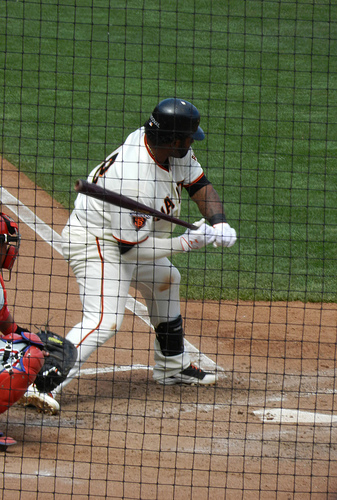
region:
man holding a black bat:
[62, 174, 250, 254]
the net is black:
[28, 184, 313, 455]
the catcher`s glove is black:
[3, 308, 90, 396]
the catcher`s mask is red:
[2, 204, 23, 265]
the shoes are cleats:
[121, 352, 227, 397]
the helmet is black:
[121, 86, 222, 164]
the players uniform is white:
[39, 73, 220, 345]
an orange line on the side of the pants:
[80, 230, 111, 354]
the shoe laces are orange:
[156, 353, 216, 385]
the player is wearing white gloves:
[164, 208, 236, 260]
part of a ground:
[169, 436, 208, 482]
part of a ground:
[278, 411, 303, 429]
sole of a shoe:
[30, 397, 48, 415]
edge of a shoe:
[184, 374, 201, 386]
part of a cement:
[244, 450, 268, 468]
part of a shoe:
[206, 368, 219, 385]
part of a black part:
[189, 363, 205, 379]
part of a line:
[152, 396, 188, 431]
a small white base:
[250, 404, 336, 428]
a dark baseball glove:
[35, 329, 79, 393]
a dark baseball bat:
[70, 179, 205, 230]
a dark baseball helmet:
[148, 98, 209, 144]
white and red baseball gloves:
[180, 218, 215, 252]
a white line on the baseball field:
[0, 180, 228, 380]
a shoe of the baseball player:
[155, 362, 217, 387]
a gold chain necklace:
[144, 140, 156, 161]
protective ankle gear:
[152, 316, 185, 353]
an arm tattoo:
[191, 186, 224, 215]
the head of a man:
[141, 91, 210, 159]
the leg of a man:
[39, 232, 135, 387]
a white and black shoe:
[155, 356, 234, 386]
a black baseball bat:
[71, 178, 205, 230]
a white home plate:
[248, 401, 336, 426]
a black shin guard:
[152, 311, 187, 357]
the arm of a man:
[180, 156, 223, 220]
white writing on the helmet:
[147, 113, 162, 129]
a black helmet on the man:
[142, 94, 207, 141]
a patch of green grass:
[0, 0, 336, 307]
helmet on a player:
[141, 96, 211, 150]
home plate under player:
[257, 389, 319, 442]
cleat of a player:
[167, 350, 219, 392]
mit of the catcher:
[32, 328, 73, 393]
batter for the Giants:
[73, 111, 220, 305]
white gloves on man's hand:
[179, 213, 238, 255]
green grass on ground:
[241, 115, 314, 191]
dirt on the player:
[154, 265, 183, 296]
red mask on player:
[0, 193, 27, 263]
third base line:
[6, 152, 41, 210]